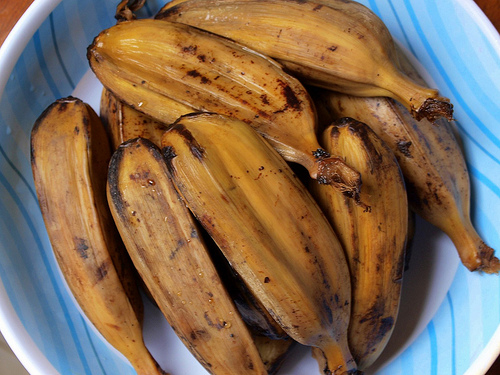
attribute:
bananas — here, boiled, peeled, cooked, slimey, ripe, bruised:
[41, 33, 490, 343]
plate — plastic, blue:
[0, 5, 76, 72]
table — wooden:
[4, 6, 27, 30]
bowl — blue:
[15, 276, 92, 340]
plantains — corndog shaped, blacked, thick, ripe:
[75, 164, 290, 287]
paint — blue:
[28, 34, 122, 75]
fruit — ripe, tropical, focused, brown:
[258, 131, 427, 286]